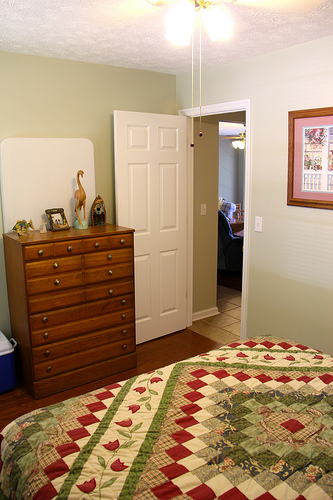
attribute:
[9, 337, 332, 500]
quilt — green, red, colorful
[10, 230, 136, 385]
chest of drawers — wooden, brown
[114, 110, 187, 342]
door — white, wooden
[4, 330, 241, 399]
wooden floor — brown, hardwood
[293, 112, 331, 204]
picture on wall — pink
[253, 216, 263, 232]
light switch — white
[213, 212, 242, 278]
recliner — blue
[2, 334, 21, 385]
cooler — blue, white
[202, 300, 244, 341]
tile flooring — beige